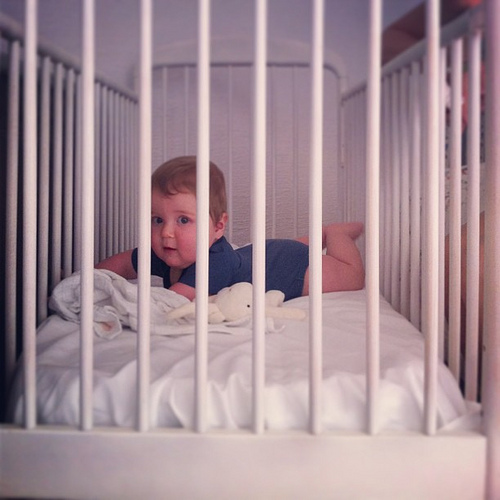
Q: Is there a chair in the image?
A: No, there are no chairs.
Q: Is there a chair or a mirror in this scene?
A: No, there are no chairs or mirrors.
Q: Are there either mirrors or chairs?
A: No, there are no chairs or mirrors.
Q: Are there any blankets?
A: Yes, there is a blanket.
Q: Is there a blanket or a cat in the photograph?
A: Yes, there is a blanket.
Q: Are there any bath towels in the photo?
A: No, there are no bath towels.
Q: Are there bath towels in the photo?
A: No, there are no bath towels.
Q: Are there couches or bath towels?
A: No, there are no bath towels or couches.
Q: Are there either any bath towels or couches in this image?
A: No, there are no bath towels or couches.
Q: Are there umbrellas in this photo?
A: No, there are no umbrellas.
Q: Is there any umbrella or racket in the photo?
A: No, there are no umbrellas or rackets.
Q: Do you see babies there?
A: Yes, there is a baby.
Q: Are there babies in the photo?
A: Yes, there is a baby.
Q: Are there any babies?
A: Yes, there is a baby.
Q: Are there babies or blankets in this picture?
A: Yes, there is a baby.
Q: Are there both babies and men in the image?
A: No, there is a baby but no men.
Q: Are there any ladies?
A: No, there are no ladies.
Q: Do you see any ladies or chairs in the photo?
A: No, there are no ladies or chairs.